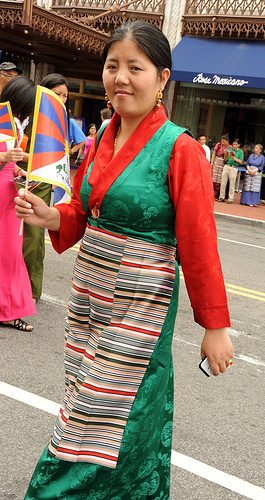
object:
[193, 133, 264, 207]
pedestrians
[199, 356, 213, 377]
cell phone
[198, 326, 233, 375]
hand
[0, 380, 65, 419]
white line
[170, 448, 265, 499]
white line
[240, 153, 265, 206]
dress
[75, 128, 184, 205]
striped front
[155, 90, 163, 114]
ear rings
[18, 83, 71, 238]
flag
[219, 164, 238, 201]
pants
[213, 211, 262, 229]
curb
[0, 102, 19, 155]
flag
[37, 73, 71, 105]
woman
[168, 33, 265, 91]
awning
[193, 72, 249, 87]
lettering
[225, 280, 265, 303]
line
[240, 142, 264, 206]
people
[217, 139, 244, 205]
people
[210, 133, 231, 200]
people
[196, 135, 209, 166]
people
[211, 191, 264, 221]
sidewalk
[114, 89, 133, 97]
mouth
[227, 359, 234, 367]
ring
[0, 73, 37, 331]
boarder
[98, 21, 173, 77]
dark hair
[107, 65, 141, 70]
eyes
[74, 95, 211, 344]
shirt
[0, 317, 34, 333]
sandal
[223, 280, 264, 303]
yellow lines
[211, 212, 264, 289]
road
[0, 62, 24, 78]
cap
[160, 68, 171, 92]
ear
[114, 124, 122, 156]
necklace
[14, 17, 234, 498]
girl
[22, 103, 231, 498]
dress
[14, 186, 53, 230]
hand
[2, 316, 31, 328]
foot